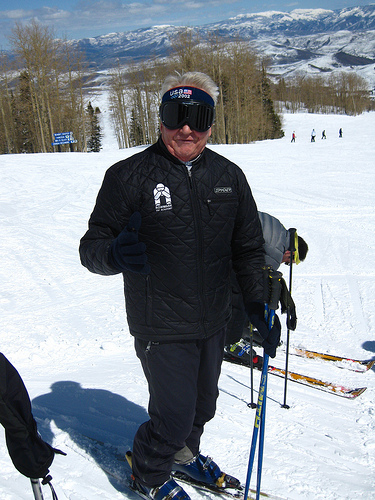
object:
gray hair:
[160, 71, 220, 109]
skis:
[223, 342, 375, 399]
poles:
[243, 264, 283, 500]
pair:
[243, 264, 283, 500]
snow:
[302, 451, 374, 497]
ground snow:
[252, 137, 288, 200]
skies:
[63, 426, 286, 500]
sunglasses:
[160, 98, 216, 132]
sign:
[51, 131, 78, 146]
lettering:
[51, 132, 77, 146]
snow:
[7, 284, 42, 318]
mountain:
[0, 0, 375, 135]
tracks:
[31, 387, 151, 474]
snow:
[108, 352, 128, 383]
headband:
[159, 85, 214, 110]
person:
[224, 211, 309, 368]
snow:
[7, 165, 68, 264]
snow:
[306, 141, 357, 209]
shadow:
[31, 380, 155, 500]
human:
[78, 70, 281, 500]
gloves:
[110, 212, 151, 274]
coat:
[79, 133, 266, 341]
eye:
[162, 113, 183, 129]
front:
[332, 354, 375, 399]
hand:
[245, 302, 282, 358]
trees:
[0, 18, 62, 155]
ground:
[340, 89, 373, 183]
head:
[159, 70, 220, 162]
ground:
[6, 161, 76, 319]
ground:
[281, 418, 328, 493]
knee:
[233, 295, 249, 327]